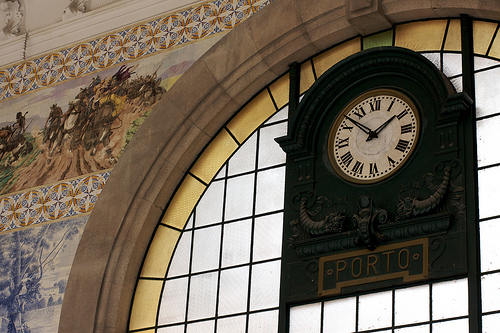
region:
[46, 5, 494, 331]
THIS IS A WINDOW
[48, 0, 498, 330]
THE WINDOW IS AN ARCH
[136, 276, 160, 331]
THE GLASS IS YELLOW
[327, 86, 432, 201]
THIS IS A CLOCK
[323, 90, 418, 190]
THE CLOCK IS ON THE WINDOW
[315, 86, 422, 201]
THE CLOCK HAS A WHITE FACE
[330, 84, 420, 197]
THE CLOCK HAS BLACK HANDS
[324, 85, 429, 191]
THE CLOCK HAS ROMAN NUMERALS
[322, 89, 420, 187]
THE ROMAN NUMERALS ARE BLACK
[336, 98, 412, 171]
THE TIME ON THE CLOCK IS 1:52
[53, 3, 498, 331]
this is a window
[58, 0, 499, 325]
the window is an arch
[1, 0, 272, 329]
the wall is very colorful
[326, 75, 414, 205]
this is a clock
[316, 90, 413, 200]
the numbers are roman numerals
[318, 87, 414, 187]
the face is white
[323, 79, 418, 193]
the numbers are black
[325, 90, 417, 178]
the hands are black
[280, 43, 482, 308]
the frame is green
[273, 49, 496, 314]
the frame is decorative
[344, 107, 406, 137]
ten minutes to two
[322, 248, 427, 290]
the writings are in bold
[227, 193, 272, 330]
this is a window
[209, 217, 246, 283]
the window is made of glass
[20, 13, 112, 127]
this is a wall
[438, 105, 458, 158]
the object is black in color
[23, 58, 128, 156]
there are some drawings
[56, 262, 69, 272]
the wall is blue in color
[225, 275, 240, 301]
the window is white in color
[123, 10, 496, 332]
THE GLASS IS YELLOW AND WHITE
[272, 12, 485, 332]
THE CLOCK IS ON THE WINDOW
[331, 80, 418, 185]
THE CLOCK IS WHITE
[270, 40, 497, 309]
THE CLOCK IS IN A DARK GREEN FRAME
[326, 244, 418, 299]
THE CLOCK SAYS PORTO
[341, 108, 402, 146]
THE CLOCK HAS BLACK HANDS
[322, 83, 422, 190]
THE FACE OF THE CLOCK IS WHITE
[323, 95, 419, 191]
the clock is circular shaped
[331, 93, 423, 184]
it is 1.53 on the clock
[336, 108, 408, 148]
the minute hand is black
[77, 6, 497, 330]
the window is arched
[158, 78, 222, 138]
the frame is made of stone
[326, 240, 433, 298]
porto letters are brown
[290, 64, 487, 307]
the frame ismettalic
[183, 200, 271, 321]
the window has sqaure tiles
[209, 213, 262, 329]
light is coming through the window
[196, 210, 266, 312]
it is daylight outside